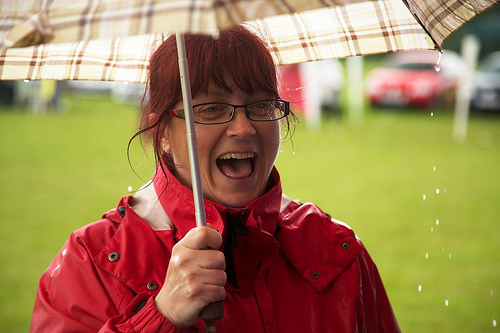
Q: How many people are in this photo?
A: One.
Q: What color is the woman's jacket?
A: Red.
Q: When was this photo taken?
A: Daytime.